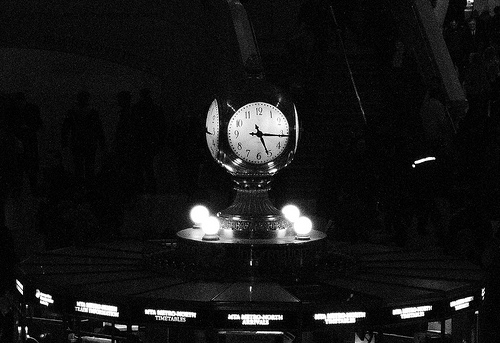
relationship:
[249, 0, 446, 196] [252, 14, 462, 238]
people on stairs